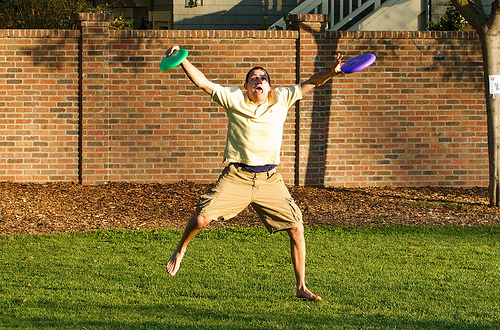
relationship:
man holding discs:
[138, 34, 396, 308] [150, 38, 381, 83]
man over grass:
[138, 34, 396, 308] [6, 228, 498, 328]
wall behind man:
[6, 11, 499, 186] [138, 34, 396, 308]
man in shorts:
[138, 34, 396, 308] [190, 154, 309, 240]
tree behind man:
[442, 0, 500, 208] [138, 34, 396, 308]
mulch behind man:
[1, 177, 498, 230] [138, 34, 396, 308]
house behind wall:
[83, 0, 499, 32] [6, 11, 499, 186]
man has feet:
[138, 34, 396, 308] [144, 251, 340, 304]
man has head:
[138, 34, 396, 308] [236, 65, 276, 107]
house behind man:
[83, 0, 499, 32] [138, 34, 396, 308]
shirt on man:
[208, 83, 296, 165] [138, 34, 396, 308]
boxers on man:
[230, 159, 278, 176] [138, 34, 396, 308]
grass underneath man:
[6, 228, 498, 328] [138, 34, 396, 308]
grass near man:
[6, 228, 498, 328] [138, 34, 396, 308]